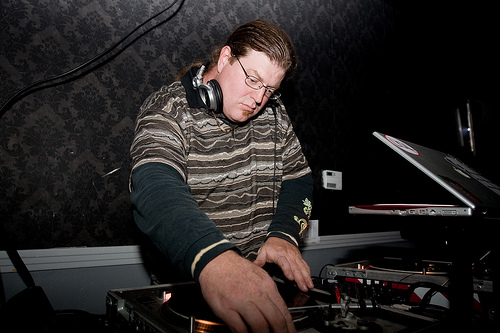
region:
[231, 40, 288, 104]
man wearing reading glasses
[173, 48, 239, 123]
man with ear phones on his head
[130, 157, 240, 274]
man wearing a long sleeve shirt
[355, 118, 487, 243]
laptop in front of the man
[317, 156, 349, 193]
control switch on the wall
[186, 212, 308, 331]
man using DJ equipment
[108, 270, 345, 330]
man using a record player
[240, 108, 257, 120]
man with a goatee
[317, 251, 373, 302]
wires on a record people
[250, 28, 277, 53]
man with brown hair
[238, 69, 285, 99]
man wearing reading glasses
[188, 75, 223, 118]
ear muff on shoulder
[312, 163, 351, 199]
temperature panel on wall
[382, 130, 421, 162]
white sticker on laptop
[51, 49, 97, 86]
black wire on wall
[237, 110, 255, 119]
brown hair on chin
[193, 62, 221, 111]
The man is wearing headphones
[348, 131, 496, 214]
A laptop above the DJ machines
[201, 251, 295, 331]
The right hand of the man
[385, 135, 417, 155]
A sticker on the computer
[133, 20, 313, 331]
A man performing as a DJ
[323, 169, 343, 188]
A white control box on the wall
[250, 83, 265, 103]
The nose of the man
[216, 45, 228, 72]
The right ear of the man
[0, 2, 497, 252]
A wall behind the man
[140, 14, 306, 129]
a man with headphones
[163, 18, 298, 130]
a man with headphones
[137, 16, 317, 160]
a man with headphones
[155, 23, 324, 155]
a man with headphones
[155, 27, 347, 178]
a man with headphones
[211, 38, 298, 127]
man is wearing eyeglasses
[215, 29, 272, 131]
man is wearing eyeglasses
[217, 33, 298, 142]
man is wearing eyeglasses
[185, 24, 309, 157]
man is wearing eyeglasses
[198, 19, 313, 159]
man is wearing eyeglasses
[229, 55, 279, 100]
a pair of glasses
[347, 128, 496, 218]
a gray laptop computer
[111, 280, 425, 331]
a turn table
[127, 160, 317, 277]
green long sleeves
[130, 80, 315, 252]
striped short sleeve shirt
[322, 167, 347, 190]
white panel on wall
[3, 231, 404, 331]
a piece of white trim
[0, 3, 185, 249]
a dangling black cord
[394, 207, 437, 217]
ports on a computer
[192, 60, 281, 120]
a pair of headphones around neck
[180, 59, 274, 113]
black and silver headphone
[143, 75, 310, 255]
brown striped shirt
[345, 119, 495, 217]
open silver laptop near the man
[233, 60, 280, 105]
eyeglasses man is wearing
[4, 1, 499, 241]
wall behind the man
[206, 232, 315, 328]
hands of the man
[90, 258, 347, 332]
record player in the front of the man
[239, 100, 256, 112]
mouth of the man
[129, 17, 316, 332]
the man has brown hair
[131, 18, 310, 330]
the man is wearing a striped shirt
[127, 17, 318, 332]
the man is standing up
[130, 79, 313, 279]
the shirt has long sleeves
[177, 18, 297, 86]
the hair is brown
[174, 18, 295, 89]
the hair is medium length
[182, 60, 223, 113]
the headset is black and silver